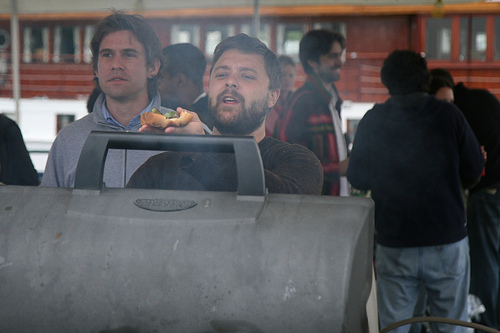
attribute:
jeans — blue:
[374, 239, 475, 331]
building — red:
[1, 0, 499, 150]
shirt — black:
[449, 77, 497, 179]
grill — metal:
[3, 111, 425, 325]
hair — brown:
[219, 26, 283, 62]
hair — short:
[215, 33, 274, 54]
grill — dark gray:
[2, 144, 372, 302]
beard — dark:
[293, 25, 346, 95]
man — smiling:
[358, 42, 480, 330]